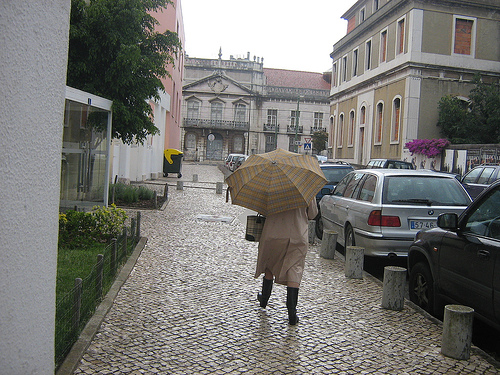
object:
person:
[242, 167, 319, 325]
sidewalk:
[64, 160, 496, 373]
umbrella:
[227, 149, 328, 216]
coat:
[255, 195, 320, 291]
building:
[175, 58, 331, 165]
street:
[293, 159, 493, 368]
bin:
[163, 147, 182, 177]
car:
[318, 169, 474, 263]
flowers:
[412, 140, 444, 152]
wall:
[0, 0, 495, 375]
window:
[452, 15, 478, 57]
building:
[327, 0, 495, 168]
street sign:
[299, 137, 313, 154]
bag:
[244, 216, 267, 239]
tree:
[437, 72, 497, 143]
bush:
[58, 208, 120, 245]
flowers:
[58, 206, 122, 236]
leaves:
[461, 103, 498, 126]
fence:
[57, 207, 142, 367]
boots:
[280, 284, 300, 322]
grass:
[60, 233, 96, 280]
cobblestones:
[103, 163, 499, 373]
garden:
[54, 207, 136, 375]